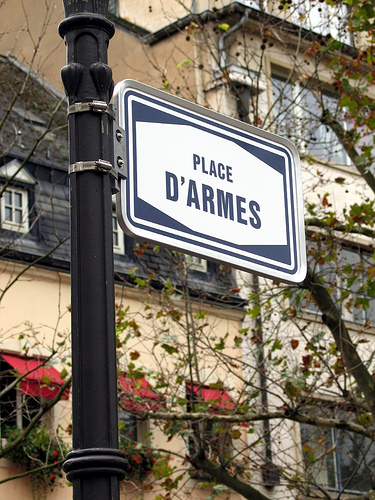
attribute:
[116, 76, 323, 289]
sign — is blue, white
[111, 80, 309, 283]
sign — is white, is blue, blue, white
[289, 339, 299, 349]
flowers — are red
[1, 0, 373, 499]
building — brown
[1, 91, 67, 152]
roof — gray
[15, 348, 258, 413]
canopies — are red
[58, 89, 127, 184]
clamp — chrome, metal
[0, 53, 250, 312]
roof — is black, black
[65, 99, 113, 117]
bracket — is silver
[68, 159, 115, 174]
bracket — is silver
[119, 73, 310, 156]
trim — metal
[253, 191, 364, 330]
floor — second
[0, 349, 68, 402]
window covering — red